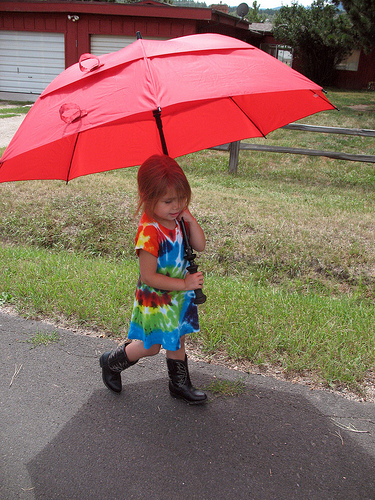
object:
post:
[241, 143, 375, 164]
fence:
[221, 120, 373, 177]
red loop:
[55, 99, 92, 124]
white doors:
[0, 27, 63, 96]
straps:
[55, 97, 84, 124]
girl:
[98, 146, 208, 407]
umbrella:
[0, 27, 338, 185]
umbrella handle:
[145, 105, 212, 306]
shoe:
[165, 352, 208, 405]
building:
[1, 0, 250, 107]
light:
[64, 12, 81, 23]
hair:
[131, 153, 194, 219]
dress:
[127, 208, 202, 351]